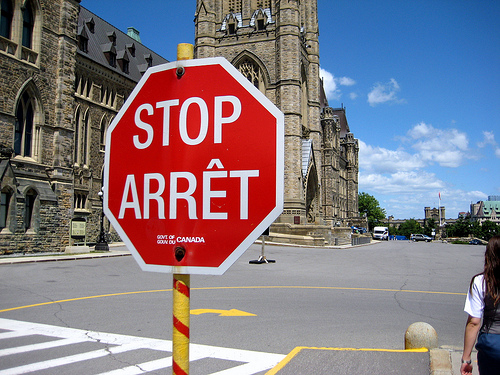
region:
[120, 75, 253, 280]
Red sign attached to pole.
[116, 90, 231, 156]
White lettering on red sign.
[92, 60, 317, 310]
White edging on sign.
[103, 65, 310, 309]
Sign says stop and has 8 sides.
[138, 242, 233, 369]
Yellow and red pole connected to sign.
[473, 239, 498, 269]
Person has brown hair.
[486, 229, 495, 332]
Person has long hair.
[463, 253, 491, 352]
Person wearing white shirt.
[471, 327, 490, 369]
Person wearing blue pants.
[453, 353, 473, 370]
Silver band around person's wrist.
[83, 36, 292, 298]
bilingual stop sign on a pole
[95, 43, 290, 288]
red and white stop sign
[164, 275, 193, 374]
red and yellow striped pole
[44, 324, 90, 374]
white paint on pavement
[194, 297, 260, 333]
yellow arrow on the pavement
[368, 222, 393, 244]
white van parked by a church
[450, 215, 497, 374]
woman walking on the road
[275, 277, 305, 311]
yellow line painted on the road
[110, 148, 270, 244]
stop written in french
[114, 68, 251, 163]
stop written in english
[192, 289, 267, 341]
Yellow arrow painted on road.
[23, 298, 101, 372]
White lines marking pavement.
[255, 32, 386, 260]
Large building on side of road.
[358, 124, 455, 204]
White clouds in sky.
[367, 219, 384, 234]
White bus near building.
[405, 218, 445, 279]
Silver car parked in lot in distance.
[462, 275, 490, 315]
Person wearing white shirt.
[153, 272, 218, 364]
Red stripes on yellow pole.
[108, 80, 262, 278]
Red stop sign on road.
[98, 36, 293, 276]
Stop sign on next to sidewalk and street.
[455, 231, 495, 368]
Woman walking down sidewalk.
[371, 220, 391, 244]
White bus parked on side of street.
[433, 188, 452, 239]
Flag on flag pole.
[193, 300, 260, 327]
Yellow traffic directional arrow painted on street.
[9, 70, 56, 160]
Window on side of gothic-like building.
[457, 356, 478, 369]
Woman wearing watch on left wrist.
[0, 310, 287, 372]
White crosswalk stripes painted on street.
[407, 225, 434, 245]
Gray car parked in parking lot.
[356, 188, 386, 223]
Trees growing in distance.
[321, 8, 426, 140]
part of a cloud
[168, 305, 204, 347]
part of a post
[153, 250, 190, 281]
edge of a boarf